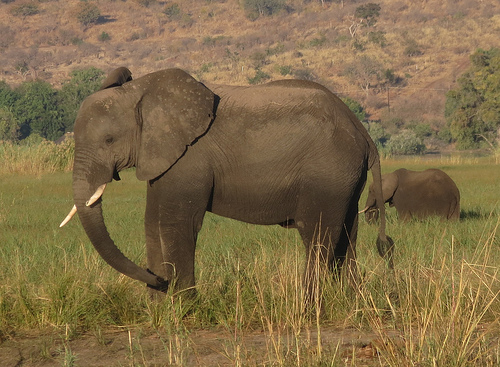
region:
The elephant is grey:
[42, 52, 392, 304]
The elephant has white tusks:
[48, 135, 133, 235]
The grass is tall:
[198, 225, 498, 353]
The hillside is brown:
[22, 7, 484, 138]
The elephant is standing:
[63, 52, 385, 310]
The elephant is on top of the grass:
[55, 65, 372, 342]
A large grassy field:
[23, 87, 468, 319]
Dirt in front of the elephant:
[26, 299, 475, 358]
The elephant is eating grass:
[351, 153, 468, 257]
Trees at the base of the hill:
[12, 65, 486, 165]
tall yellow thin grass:
[396, 271, 492, 359]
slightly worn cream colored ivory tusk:
[54, 198, 76, 225]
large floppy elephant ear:
[136, 68, 219, 183]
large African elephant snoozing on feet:
[55, 52, 393, 301]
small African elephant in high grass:
[365, 165, 463, 232]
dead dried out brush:
[136, 34, 195, 62]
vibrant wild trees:
[3, 82, 65, 144]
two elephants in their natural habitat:
[55, 43, 462, 298]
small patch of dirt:
[192, 330, 228, 365]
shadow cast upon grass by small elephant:
[460, 204, 487, 219]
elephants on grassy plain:
[30, 45, 470, 317]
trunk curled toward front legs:
[45, 100, 185, 310]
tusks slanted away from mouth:
[40, 170, 130, 230]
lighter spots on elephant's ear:
[90, 66, 236, 181]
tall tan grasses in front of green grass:
[70, 215, 480, 352]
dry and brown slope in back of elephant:
[25, 0, 475, 80]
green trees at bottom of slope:
[0, 52, 496, 147]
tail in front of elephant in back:
[356, 120, 398, 277]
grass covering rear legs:
[265, 207, 365, 302]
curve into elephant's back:
[391, 155, 441, 185]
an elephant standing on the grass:
[41, 63, 409, 320]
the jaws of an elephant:
[58, 182, 110, 231]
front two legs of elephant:
[150, 215, 214, 332]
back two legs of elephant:
[301, 213, 377, 310]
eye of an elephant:
[86, 122, 123, 146]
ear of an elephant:
[136, 77, 215, 187]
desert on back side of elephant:
[26, 10, 498, 117]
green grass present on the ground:
[126, 272, 498, 364]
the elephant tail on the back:
[366, 154, 407, 269]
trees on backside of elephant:
[4, 81, 101, 136]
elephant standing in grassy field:
[52, 63, 399, 324]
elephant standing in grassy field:
[361, 159, 463, 234]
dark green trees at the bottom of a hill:
[1, 62, 113, 147]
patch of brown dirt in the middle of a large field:
[0, 303, 498, 365]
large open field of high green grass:
[1, 151, 498, 334]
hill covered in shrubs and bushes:
[0, 0, 498, 160]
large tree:
[443, 38, 497, 172]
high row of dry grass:
[108, 209, 498, 366]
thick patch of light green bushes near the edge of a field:
[1, 131, 90, 178]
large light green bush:
[383, 123, 430, 159]